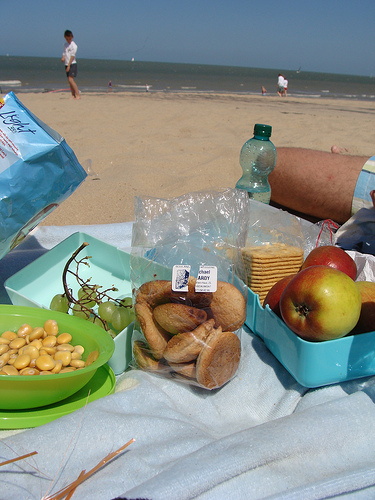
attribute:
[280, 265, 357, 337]
apple — green, red, large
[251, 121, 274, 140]
lid — green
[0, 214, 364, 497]
blanket — blue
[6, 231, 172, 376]
container — blue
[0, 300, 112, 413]
bowl — green, large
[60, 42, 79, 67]
shirt — white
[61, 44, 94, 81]
arm of a person — of a person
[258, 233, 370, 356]
colored apple — red, green